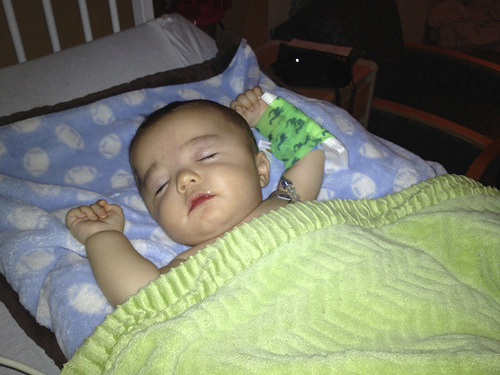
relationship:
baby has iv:
[57, 93, 386, 301] [277, 175, 304, 209]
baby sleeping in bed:
[57, 93, 386, 301] [2, 3, 500, 375]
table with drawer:
[259, 47, 376, 141] [344, 83, 374, 121]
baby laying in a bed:
[57, 93, 386, 301] [2, 3, 500, 375]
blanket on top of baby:
[62, 174, 498, 374] [57, 93, 386, 301]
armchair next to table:
[284, 8, 500, 175] [259, 47, 376, 141]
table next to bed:
[259, 47, 376, 141] [2, 3, 500, 375]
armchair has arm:
[284, 8, 500, 175] [377, 92, 493, 180]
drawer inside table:
[344, 83, 374, 121] [259, 47, 376, 141]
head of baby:
[133, 99, 272, 237] [57, 93, 386, 301]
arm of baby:
[245, 89, 323, 201] [57, 93, 386, 301]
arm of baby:
[73, 196, 163, 299] [57, 93, 386, 301]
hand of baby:
[227, 82, 269, 124] [57, 93, 386, 301]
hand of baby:
[60, 199, 128, 236] [57, 93, 386, 301]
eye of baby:
[196, 148, 222, 163] [57, 93, 386, 301]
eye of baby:
[154, 180, 174, 202] [57, 93, 386, 301]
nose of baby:
[175, 169, 203, 191] [57, 93, 386, 301]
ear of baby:
[257, 150, 271, 188] [57, 93, 386, 301]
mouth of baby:
[182, 191, 217, 211] [57, 93, 386, 301]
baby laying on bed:
[57, 93, 386, 301] [2, 3, 500, 375]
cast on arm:
[258, 90, 350, 170] [245, 89, 323, 201]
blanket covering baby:
[62, 174, 498, 374] [57, 93, 386, 301]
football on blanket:
[99, 134, 121, 160] [4, 38, 451, 355]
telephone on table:
[286, 49, 362, 109] [259, 47, 376, 141]